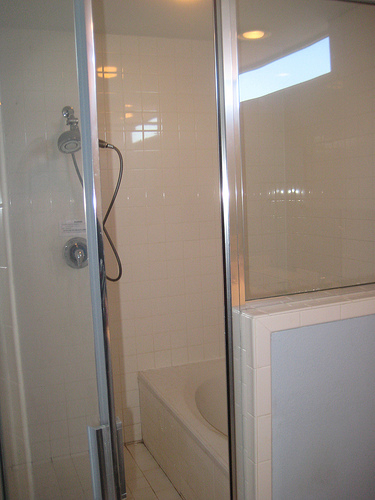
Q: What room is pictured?
A: It is a bathroom.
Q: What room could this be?
A: It is a bathroom.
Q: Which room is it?
A: It is a bathroom.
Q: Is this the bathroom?
A: Yes, it is the bathroom.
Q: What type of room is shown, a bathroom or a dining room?
A: It is a bathroom.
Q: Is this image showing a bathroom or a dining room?
A: It is showing a bathroom.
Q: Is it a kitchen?
A: No, it is a bathroom.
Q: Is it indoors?
A: Yes, it is indoors.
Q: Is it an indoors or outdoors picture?
A: It is indoors.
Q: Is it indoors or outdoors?
A: It is indoors.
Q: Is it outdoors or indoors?
A: It is indoors.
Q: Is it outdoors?
A: No, it is indoors.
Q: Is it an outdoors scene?
A: No, it is indoors.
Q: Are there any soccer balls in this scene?
A: No, there are no soccer balls.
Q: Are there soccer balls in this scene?
A: No, there are no soccer balls.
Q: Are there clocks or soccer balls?
A: No, there are no soccer balls or clocks.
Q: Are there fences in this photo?
A: No, there are no fences.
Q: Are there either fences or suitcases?
A: No, there are no fences or suitcases.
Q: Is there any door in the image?
A: Yes, there is a door.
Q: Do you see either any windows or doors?
A: Yes, there is a door.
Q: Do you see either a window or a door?
A: Yes, there is a door.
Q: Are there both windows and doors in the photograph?
A: Yes, there are both a door and a window.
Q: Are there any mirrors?
A: No, there are no mirrors.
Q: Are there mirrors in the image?
A: No, there are no mirrors.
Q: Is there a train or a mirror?
A: No, there are no mirrors or trains.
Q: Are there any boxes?
A: No, there are no boxes.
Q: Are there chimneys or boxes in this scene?
A: No, there are no boxes or chimneys.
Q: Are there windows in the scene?
A: Yes, there is a window.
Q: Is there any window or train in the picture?
A: Yes, there is a window.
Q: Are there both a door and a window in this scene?
A: Yes, there are both a window and a door.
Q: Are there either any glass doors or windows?
A: Yes, there is a glass window.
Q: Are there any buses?
A: No, there are no buses.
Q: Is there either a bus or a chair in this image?
A: No, there are no buses or chairs.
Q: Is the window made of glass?
A: Yes, the window is made of glass.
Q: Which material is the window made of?
A: The window is made of glass.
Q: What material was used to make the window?
A: The window is made of glass.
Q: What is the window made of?
A: The window is made of glass.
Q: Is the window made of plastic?
A: No, the window is made of glass.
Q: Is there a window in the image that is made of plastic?
A: No, there is a window but it is made of glass.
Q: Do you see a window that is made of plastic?
A: No, there is a window but it is made of glass.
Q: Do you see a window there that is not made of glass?
A: No, there is a window but it is made of glass.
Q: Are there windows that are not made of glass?
A: No, there is a window but it is made of glass.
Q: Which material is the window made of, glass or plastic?
A: The window is made of glass.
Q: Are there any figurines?
A: No, there are no figurines.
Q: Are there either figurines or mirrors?
A: No, there are no figurines or mirrors.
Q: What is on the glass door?
A: The bathtub is on the door.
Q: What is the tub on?
A: The tub is on the door.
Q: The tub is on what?
A: The tub is on the door.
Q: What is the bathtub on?
A: The tub is on the door.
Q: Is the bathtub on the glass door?
A: Yes, the bathtub is on the door.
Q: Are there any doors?
A: Yes, there is a door.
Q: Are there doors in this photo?
A: Yes, there is a door.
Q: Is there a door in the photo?
A: Yes, there is a door.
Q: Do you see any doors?
A: Yes, there is a door.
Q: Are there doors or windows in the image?
A: Yes, there is a door.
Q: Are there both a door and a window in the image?
A: Yes, there are both a door and a window.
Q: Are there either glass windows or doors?
A: Yes, there is a glass door.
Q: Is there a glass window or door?
A: Yes, there is a glass door.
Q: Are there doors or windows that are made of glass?
A: Yes, the door is made of glass.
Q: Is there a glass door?
A: Yes, there is a door that is made of glass.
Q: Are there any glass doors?
A: Yes, there is a door that is made of glass.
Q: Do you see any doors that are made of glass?
A: Yes, there is a door that is made of glass.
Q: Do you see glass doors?
A: Yes, there is a door that is made of glass.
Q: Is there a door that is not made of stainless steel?
A: Yes, there is a door that is made of glass.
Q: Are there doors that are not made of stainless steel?
A: Yes, there is a door that is made of glass.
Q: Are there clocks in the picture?
A: No, there are no clocks.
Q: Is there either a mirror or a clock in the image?
A: No, there are no clocks or mirrors.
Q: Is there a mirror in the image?
A: No, there are no mirrors.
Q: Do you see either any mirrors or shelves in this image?
A: No, there are no mirrors or shelves.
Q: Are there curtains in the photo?
A: No, there are no curtains.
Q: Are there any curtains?
A: No, there are no curtains.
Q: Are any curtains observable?
A: No, there are no curtains.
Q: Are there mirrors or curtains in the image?
A: No, there are no curtains or mirrors.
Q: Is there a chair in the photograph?
A: No, there are no chairs.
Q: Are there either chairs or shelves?
A: No, there are no chairs or shelves.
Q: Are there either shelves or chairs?
A: No, there are no chairs or shelves.